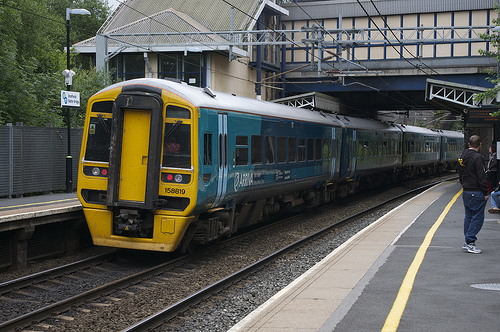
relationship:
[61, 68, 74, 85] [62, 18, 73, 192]
box on pole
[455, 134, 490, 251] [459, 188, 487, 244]
man wearing pants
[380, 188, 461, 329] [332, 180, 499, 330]
line on pavement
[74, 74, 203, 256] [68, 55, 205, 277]
front of train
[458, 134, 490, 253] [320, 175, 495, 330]
man on platform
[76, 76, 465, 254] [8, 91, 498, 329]
front at station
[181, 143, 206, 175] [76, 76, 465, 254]
edge of front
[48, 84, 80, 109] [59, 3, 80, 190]
sign on pole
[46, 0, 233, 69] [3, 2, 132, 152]
cords going across trees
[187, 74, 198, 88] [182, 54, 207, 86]
white sign on window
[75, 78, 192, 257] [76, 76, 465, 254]
yellow front on front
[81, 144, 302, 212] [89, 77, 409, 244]
lights on front of train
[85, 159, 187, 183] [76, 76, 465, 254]
lights on front of front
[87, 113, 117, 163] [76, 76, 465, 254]
windshield on front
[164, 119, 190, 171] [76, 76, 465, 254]
windshield on front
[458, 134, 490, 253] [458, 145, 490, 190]
man wearing jacket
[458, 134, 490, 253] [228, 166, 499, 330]
man standing in platform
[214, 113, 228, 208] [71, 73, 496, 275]
door on left side train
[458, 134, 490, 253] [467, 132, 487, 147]
man has hair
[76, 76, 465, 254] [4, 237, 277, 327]
front on tracks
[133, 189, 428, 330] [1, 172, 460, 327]
gravel along tracks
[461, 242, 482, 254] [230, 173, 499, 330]
shoe on pavement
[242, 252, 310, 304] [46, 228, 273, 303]
gravel on tracks